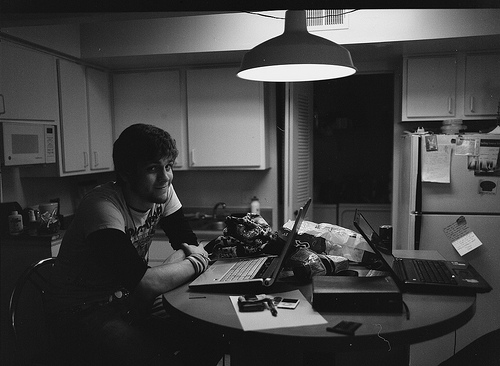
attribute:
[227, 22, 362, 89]
light — bright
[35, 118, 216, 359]
man — working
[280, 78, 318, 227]
door — open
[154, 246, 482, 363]
table — kitchen